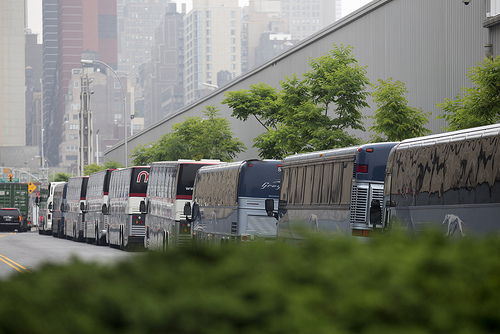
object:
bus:
[254, 130, 411, 254]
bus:
[48, 182, 66, 237]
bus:
[35, 123, 500, 253]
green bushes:
[0, 221, 499, 334]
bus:
[101, 166, 151, 251]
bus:
[61, 176, 90, 242]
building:
[183, 7, 242, 106]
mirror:
[265, 199, 275, 211]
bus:
[264, 141, 400, 243]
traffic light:
[8, 174, 13, 182]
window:
[206, 21, 208, 27]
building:
[142, 3, 183, 129]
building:
[0, 0, 117, 167]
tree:
[132, 107, 245, 165]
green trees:
[219, 45, 429, 159]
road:
[0, 225, 143, 281]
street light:
[80, 59, 128, 169]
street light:
[96, 129, 100, 166]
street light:
[34, 156, 54, 167]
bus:
[369, 122, 500, 246]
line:
[0, 232, 34, 276]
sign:
[28, 181, 37, 194]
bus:
[183, 160, 283, 247]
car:
[0, 208, 23, 232]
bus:
[80, 169, 117, 245]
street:
[0, 214, 147, 277]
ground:
[1, 230, 159, 282]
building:
[57, 49, 132, 177]